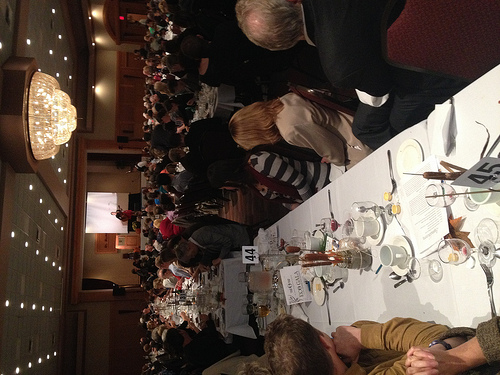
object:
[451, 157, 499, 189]
sign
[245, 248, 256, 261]
44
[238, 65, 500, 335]
table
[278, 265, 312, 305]
name card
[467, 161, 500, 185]
45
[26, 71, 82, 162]
chandelier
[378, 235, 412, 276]
cup and saucer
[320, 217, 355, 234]
wineglass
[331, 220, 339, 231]
red wine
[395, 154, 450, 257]
agenda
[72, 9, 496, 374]
conference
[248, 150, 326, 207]
shirt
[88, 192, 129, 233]
screen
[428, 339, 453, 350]
watch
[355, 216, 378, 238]
cup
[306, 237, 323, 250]
cup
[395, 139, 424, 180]
plate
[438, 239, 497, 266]
glass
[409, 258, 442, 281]
glass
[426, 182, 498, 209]
glass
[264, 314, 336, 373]
head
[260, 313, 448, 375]
man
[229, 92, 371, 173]
woman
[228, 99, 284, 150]
blond hair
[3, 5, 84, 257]
ceiling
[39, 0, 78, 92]
tiny lights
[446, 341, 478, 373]
wrist